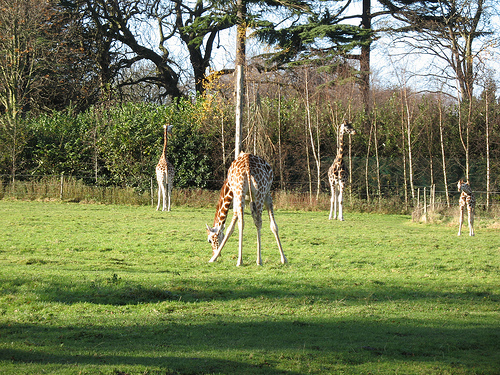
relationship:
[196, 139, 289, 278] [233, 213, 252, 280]
giraffe has leg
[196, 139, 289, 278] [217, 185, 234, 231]
giraffe has neck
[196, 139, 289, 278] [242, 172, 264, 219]
giraffe has tail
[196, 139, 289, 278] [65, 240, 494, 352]
giraffe on grass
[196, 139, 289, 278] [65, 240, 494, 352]
giraffe in grass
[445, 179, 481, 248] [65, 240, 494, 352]
giraffe in grass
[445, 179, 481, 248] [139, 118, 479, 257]
giraffe near giraffes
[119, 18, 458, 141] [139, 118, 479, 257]
trees behind giraffes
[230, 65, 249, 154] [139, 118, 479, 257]
pole behind giraffes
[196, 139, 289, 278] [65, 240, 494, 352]
giraffe eating grass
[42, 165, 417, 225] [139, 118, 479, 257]
fence behind giraffes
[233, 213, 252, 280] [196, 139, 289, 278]
leg on giraffe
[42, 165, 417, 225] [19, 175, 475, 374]
fence on field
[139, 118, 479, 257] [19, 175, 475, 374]
giraffes in field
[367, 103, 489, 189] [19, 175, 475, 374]
shrubs in field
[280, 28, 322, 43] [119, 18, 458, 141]
leaves on trees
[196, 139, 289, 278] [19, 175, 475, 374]
giraffe in field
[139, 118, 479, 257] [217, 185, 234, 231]
giraffes has neck